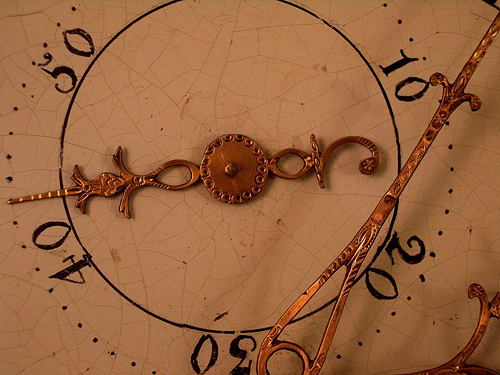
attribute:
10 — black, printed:
[379, 49, 431, 101]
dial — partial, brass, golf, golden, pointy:
[9, 130, 382, 216]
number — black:
[37, 50, 77, 95]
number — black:
[61, 26, 95, 57]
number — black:
[379, 50, 419, 77]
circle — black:
[57, 4, 403, 335]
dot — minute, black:
[22, 82, 26, 86]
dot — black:
[72, 5, 76, 11]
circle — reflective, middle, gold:
[202, 133, 269, 203]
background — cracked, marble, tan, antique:
[0, 2, 498, 373]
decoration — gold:
[411, 282, 500, 370]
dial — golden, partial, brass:
[253, 16, 499, 370]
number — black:
[395, 76, 429, 102]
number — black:
[49, 251, 91, 285]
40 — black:
[31, 220, 91, 287]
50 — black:
[38, 28, 96, 93]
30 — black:
[191, 331, 256, 373]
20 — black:
[361, 232, 424, 300]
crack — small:
[178, 26, 222, 104]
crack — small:
[329, 73, 358, 101]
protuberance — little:
[178, 322, 187, 329]